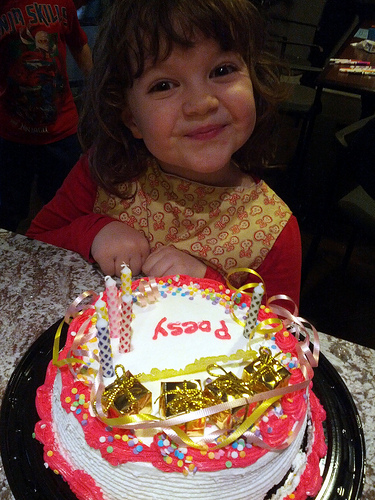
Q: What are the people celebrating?
A: A birthday.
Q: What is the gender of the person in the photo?
A: Female.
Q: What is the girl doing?
A: Smiling.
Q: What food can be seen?
A: A cake.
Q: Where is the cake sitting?
A: On the counter.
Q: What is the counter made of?
A: Granite.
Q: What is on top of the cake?
A: Candles.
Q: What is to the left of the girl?
A: A boy.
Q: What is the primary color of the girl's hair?
A: Brown.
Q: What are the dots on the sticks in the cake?
A: Candles.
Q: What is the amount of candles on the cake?
A: 6.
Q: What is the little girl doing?
A: Smiling.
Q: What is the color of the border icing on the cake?
A: Red.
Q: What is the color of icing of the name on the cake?
A: Red.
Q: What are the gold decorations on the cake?
A: Presents.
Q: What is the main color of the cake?
A: White.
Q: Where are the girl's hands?
A: On the table.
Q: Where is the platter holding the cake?
A: Beneath the cake.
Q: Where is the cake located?
A: On the table.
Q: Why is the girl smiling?
A: She is happy.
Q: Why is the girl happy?
A: Celebrating birthday.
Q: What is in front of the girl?
A: Birthday cake.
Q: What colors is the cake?
A: White and pink.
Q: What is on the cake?
A: Candles.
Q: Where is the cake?
A: On the table.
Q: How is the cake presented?
A: On a plate.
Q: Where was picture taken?
A: In a house.